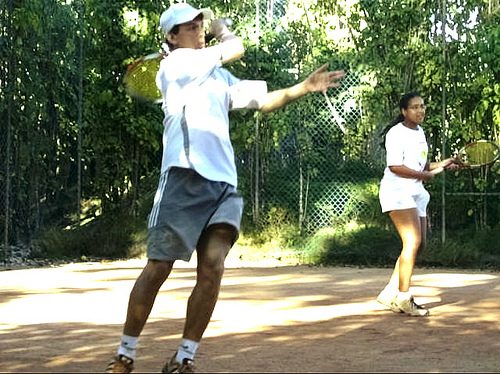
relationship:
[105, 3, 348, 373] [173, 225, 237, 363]
person has a leg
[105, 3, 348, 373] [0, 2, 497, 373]
person on a tennis court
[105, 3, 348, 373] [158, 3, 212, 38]
person has a cap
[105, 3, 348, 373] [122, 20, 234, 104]
person has a tennis racket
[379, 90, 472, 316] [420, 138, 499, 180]
girl has a racket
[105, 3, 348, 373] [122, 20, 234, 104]
person holding tennis racket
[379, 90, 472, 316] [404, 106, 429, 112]
girl has on glasses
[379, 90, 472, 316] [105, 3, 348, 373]
girl next to a person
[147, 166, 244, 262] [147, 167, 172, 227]
pants have a stripe